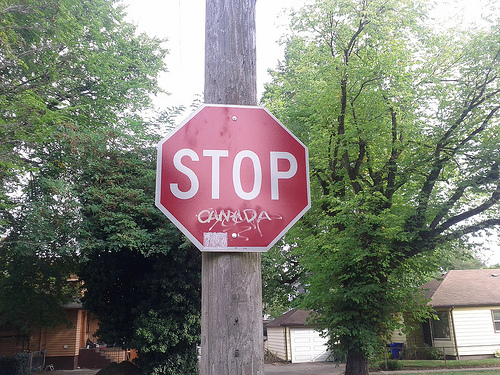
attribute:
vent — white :
[63, 345, 67, 349]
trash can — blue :
[390, 341, 404, 359]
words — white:
[194, 197, 296, 239]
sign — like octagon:
[156, 104, 313, 251]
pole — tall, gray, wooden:
[201, 0, 268, 375]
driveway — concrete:
[265, 362, 350, 372]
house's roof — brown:
[402, 253, 496, 321]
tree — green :
[262, 6, 499, 374]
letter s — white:
[167, 144, 201, 204]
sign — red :
[139, 107, 326, 256]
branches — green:
[223, 2, 499, 374]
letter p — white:
[269, 150, 296, 200]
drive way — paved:
[262, 363, 352, 373]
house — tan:
[267, 264, 499, 359]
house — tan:
[380, 269, 498, 361]